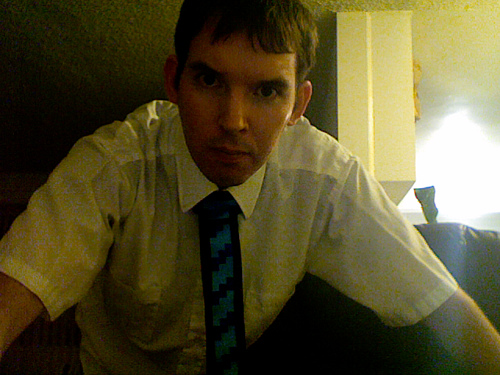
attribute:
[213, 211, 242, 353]
pattern — blue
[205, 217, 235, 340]
pattern — blue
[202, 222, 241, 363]
pattern — blue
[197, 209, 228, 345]
pattern — blue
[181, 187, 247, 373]
tie — blue, black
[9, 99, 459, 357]
shirt — white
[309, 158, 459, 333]
sleeve — short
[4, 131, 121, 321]
sleeve — short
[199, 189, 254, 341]
tie — black, blue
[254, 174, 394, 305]
shirt — white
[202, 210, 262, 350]
decorations — blue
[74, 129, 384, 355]
shirt — white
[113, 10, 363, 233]
man — serious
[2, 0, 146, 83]
roof — white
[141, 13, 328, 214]
man — serious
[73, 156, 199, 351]
shirt — white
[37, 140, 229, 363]
shirt — short sleeved, white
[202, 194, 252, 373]
tie — blue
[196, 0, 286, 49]
hair — short, brown